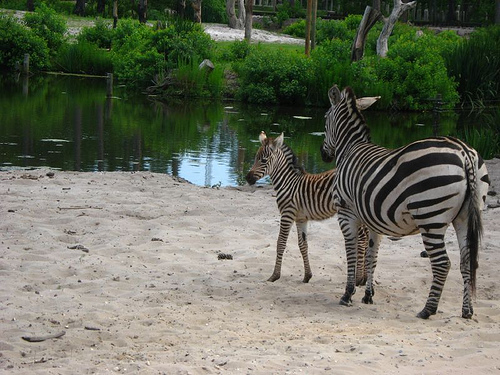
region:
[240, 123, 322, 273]
the zebra is small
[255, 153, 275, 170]
the zebra has an eye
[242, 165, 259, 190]
the zebra has a nose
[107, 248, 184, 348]
the dirt is brown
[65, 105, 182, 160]
the water is dark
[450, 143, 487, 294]
the zebra has a tail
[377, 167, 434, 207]
the stripes are black and white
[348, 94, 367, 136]
the zebra has a main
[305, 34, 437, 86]
the bushes are green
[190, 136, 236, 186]
the reflection is on the water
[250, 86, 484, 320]
Two zebras by a watering hole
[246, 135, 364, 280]
Young zebra next to adult zebra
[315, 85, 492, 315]
Adult zebra standing by young zebra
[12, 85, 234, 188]
The water looks calm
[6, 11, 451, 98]
Plants grow behind the water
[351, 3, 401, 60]
The trees are brown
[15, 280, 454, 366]
Sand is beneath the zebras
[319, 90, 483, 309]
The adult zebra is black and white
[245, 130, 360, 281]
The young zebra still has brown coloring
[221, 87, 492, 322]
The zebras are striped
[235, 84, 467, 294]
Two zebras standing by the pond.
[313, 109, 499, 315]
The zebra are standing in the sand.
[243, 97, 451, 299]
The baby zebra is standing by the mother zebra.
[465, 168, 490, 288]
The zebra has a long tail.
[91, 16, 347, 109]
The pond of water is surrounded by trees.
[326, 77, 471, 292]
The zebra is black and white.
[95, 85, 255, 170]
The reflection of the trees in the water.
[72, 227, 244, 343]
The sand has rocks.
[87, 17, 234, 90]
The small trees are green.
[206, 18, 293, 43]
Sand is on the other side of the water.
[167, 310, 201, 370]
the sand is white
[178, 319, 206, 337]
the sand is white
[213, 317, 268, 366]
the sand is white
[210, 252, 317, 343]
the sand is white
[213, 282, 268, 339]
the sand is white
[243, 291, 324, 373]
the sand is white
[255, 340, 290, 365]
the sand is white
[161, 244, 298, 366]
the sand is white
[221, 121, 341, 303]
The zebra is a baby.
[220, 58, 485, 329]
Two zebras standing next to each other.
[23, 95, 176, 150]
Trees reflected in the water.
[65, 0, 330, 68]
Trees and bushes near water.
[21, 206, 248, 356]
Sand is near the water.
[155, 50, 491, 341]
The giraffes are standing near water.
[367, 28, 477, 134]
A green bush near the water.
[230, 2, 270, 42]
The trunk of a tree.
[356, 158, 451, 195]
The zebra has black and white stripes.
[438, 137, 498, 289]
The zebra has a tail.